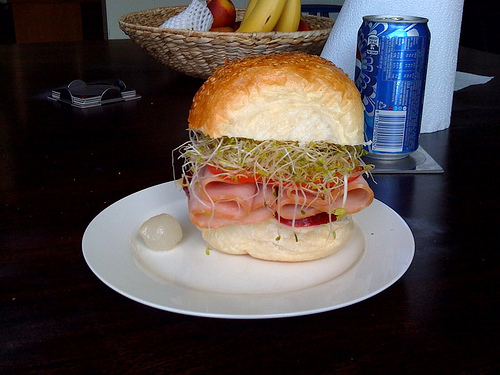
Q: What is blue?
A: The can.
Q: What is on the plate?
A: A sandwich.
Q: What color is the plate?
A: White.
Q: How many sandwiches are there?
A: One.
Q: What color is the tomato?
A: Red.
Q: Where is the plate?
A: On the table.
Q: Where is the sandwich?
A: On the plate.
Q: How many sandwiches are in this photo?
A: One.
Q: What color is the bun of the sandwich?
A: White and brown.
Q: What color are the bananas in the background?
A: Yellow.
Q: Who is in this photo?
A: No one.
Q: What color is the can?
A: Blue with white writing.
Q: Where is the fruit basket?
A: Behind the sandwich.